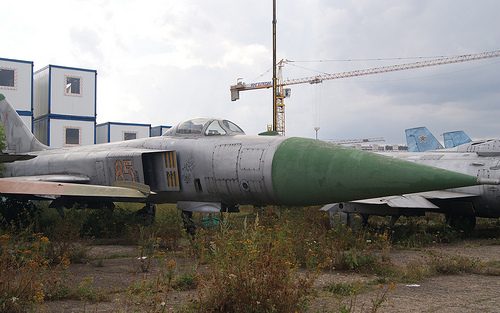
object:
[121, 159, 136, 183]
number 5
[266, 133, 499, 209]
nose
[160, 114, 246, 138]
cockpit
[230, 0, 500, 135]
crane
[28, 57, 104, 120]
rectangle boxes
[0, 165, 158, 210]
wing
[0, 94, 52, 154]
tail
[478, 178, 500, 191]
tip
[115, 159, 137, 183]
number 85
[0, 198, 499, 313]
grass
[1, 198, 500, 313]
ground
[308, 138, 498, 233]
jets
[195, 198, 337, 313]
weeds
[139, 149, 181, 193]
opening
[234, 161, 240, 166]
rivets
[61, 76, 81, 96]
window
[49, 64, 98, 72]
trim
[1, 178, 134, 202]
red paint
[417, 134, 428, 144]
star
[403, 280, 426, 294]
paper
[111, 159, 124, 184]
number 8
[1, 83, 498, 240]
plane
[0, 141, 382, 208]
side